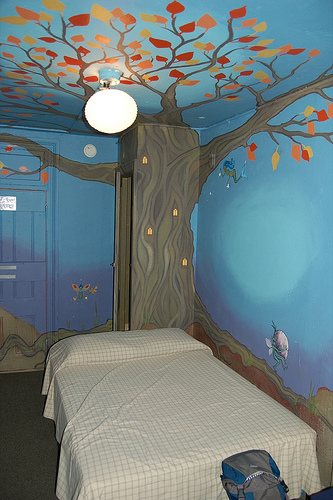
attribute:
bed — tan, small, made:
[42, 327, 321, 500]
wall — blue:
[0, 125, 333, 487]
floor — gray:
[2, 369, 332, 497]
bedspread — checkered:
[41, 327, 329, 499]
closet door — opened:
[113, 163, 135, 357]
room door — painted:
[0, 130, 66, 375]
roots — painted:
[0, 327, 330, 433]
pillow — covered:
[47, 328, 211, 367]